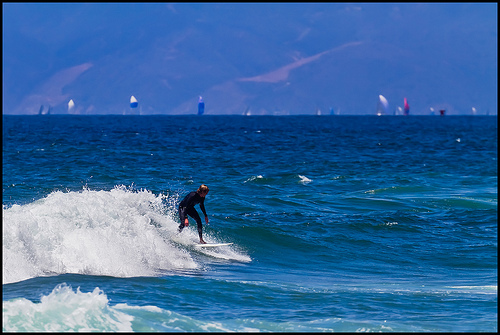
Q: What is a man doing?
A: Surfing.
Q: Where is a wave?
A: In the ocean.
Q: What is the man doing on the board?
A: The man is surfing.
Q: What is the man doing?
A: The man is surfing in the ocean.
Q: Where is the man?
A: The man is in the ocean.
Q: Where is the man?
A: The man is in the ocean.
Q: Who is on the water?
A: A surfer is on the water.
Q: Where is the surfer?
A: The surfer is in the ocean.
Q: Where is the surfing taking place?
A: In the ocean.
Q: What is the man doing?
A: Surfing in the ocean.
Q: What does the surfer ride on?
A: The surfer rides on waves.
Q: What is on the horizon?
A: The sails of ships.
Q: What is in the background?
A: The sky with angled clouds.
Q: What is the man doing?
A: Surfing.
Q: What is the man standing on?
A: A surfboard.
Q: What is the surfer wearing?
A: A black wet suit.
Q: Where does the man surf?
A: In the ocean.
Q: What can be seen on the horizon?
A: Boats.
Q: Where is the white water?
A: Behind the surfer.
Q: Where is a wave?
A: In the ocean.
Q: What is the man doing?
A: Surfing.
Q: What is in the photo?
A: Water.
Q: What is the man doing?
A: Waterboarding.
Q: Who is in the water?
A: The man.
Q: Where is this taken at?
A: A lake.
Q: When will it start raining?
A: It's not going to.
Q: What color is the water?
A: Blue.